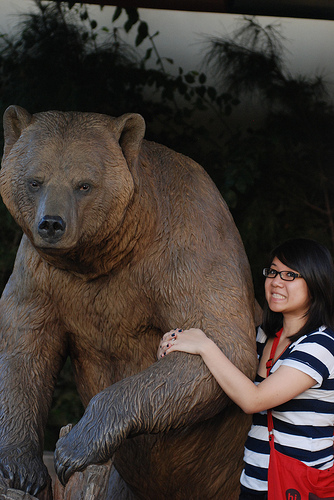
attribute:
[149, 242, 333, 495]
girl — posing, smiling, concerned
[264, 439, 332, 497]
bag — red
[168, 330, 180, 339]
finger nail — black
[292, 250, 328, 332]
hair — black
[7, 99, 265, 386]
bear statue — brown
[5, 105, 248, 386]
bear — plastic, large, weird, displayed, brown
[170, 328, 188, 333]
nail — polished, blue, dark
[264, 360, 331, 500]
purse — read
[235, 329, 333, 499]
shirt — striped, white, blue, short sleeve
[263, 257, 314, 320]
face — scary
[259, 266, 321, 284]
glasses — black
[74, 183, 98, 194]
eye — red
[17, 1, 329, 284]
bushes — dark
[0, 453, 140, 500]
log — plastic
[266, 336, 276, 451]
strap — red, long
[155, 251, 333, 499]
woman — asian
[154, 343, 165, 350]
fingernail — polished, blue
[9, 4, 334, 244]
background — forest